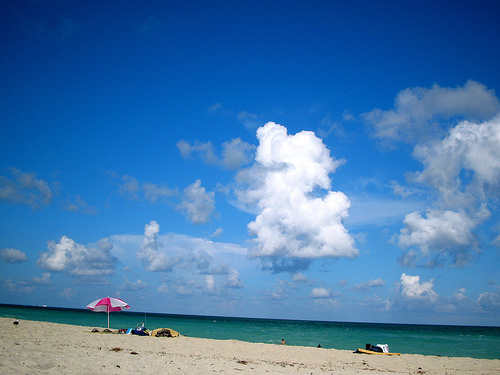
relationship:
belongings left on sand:
[117, 319, 394, 359] [2, 315, 499, 369]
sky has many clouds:
[4, 3, 500, 316] [4, 70, 500, 318]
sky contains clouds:
[4, 3, 500, 316] [4, 70, 500, 318]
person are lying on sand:
[122, 318, 146, 336] [2, 315, 499, 369]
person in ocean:
[276, 337, 288, 343] [8, 306, 500, 361]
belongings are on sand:
[117, 319, 394, 359] [2, 315, 499, 369]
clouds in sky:
[4, 70, 500, 318] [4, 3, 500, 316]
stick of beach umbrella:
[106, 308, 112, 328] [92, 294, 130, 327]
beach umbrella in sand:
[92, 294, 130, 327] [2, 315, 499, 369]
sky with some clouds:
[4, 3, 500, 316] [4, 70, 500, 318]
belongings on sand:
[117, 319, 394, 359] [2, 315, 499, 369]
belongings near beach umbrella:
[90, 321, 130, 336] [92, 294, 130, 327]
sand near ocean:
[2, 315, 499, 369] [8, 306, 500, 361]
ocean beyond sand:
[8, 306, 500, 361] [2, 315, 499, 369]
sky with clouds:
[4, 3, 500, 316] [4, 70, 500, 318]